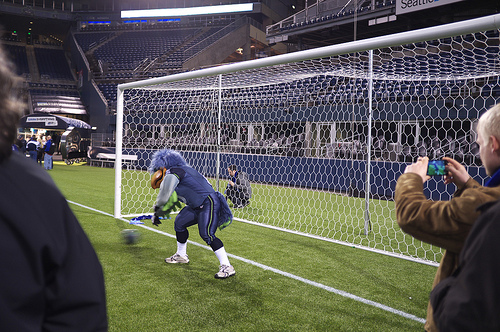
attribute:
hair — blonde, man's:
[476, 98, 498, 148]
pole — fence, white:
[113, 82, 126, 219]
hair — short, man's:
[478, 100, 498, 146]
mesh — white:
[254, 100, 382, 183]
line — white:
[127, 212, 426, 326]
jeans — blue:
[42, 151, 53, 170]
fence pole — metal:
[111, 90, 126, 217]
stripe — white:
[244, 259, 416, 330]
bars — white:
[112, 65, 413, 244]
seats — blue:
[23, 117, 108, 165]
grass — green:
[20, 141, 465, 329]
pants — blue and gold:
[173, 185, 252, 249]